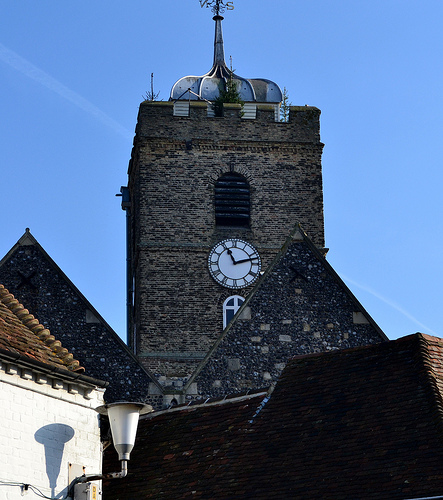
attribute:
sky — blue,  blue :
[2, 2, 440, 343]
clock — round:
[179, 215, 336, 350]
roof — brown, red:
[97, 330, 441, 498]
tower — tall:
[95, 15, 343, 395]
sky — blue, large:
[337, 51, 419, 183]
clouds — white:
[16, 58, 95, 116]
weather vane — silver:
[196, 0, 236, 12]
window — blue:
[226, 300, 239, 331]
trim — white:
[222, 293, 249, 332]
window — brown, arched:
[207, 170, 256, 226]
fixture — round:
[96, 400, 152, 479]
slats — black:
[214, 178, 250, 216]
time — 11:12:
[207, 240, 260, 281]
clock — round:
[205, 236, 267, 290]